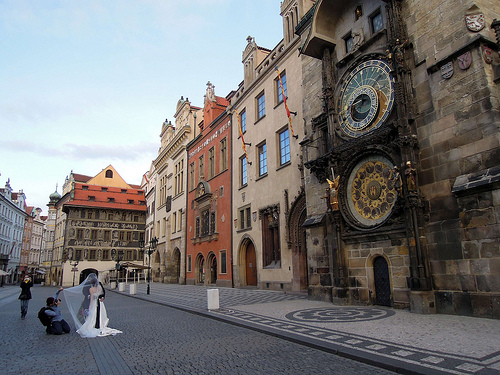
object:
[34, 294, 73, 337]
photographer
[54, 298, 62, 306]
picture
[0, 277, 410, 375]
street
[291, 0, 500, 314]
building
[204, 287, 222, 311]
rectangle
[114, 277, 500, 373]
sidewalk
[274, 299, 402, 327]
design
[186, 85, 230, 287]
building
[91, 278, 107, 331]
fabric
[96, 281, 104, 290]
shoulder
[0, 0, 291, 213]
sky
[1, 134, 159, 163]
cloud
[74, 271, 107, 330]
groom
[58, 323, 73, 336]
knees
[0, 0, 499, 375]
picture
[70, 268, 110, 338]
couple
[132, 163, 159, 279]
building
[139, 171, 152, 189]
flag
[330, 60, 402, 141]
clock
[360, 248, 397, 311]
entry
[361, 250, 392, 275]
arch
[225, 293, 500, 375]
pattern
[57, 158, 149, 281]
building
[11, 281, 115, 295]
end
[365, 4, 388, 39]
window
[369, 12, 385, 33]
glass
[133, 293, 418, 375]
line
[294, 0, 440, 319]
tower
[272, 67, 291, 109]
windows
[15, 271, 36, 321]
people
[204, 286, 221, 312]
can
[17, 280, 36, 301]
coat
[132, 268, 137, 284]
posts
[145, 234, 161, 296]
lamp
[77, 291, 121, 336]
dress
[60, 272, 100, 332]
veil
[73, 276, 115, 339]
bride